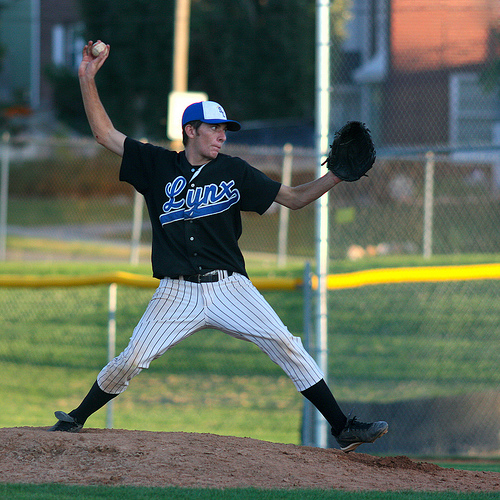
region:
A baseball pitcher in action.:
[45, 35, 390, 456]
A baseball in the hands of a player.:
[85, 37, 105, 53]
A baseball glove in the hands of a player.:
[320, 115, 375, 180]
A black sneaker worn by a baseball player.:
[325, 415, 385, 450]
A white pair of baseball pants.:
[90, 265, 321, 391]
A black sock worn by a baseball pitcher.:
[295, 375, 350, 425]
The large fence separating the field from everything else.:
[0, 0, 495, 462]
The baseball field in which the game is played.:
[0, 425, 496, 496]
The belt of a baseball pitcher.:
[165, 270, 235, 283]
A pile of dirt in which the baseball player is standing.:
[0, 427, 492, 484]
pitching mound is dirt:
[21, 400, 323, 489]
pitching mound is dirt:
[66, 430, 316, 497]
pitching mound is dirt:
[89, 397, 426, 499]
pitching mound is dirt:
[73, 371, 443, 496]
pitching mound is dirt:
[77, 398, 245, 492]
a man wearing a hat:
[123, 65, 293, 302]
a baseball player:
[6, 14, 416, 454]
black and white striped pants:
[103, 250, 375, 379]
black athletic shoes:
[28, 395, 453, 466]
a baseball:
[43, 27, 210, 139]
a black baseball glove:
[271, 87, 406, 228]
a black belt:
[111, 250, 349, 339]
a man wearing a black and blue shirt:
[68, 28, 363, 316]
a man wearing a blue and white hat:
[118, 75, 304, 227]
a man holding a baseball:
[52, 27, 431, 251]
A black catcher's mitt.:
[323, 118, 376, 184]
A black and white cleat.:
[330, 415, 386, 450]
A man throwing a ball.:
[48, 35, 388, 452]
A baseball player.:
[48, 38, 388, 450]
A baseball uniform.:
[107, 135, 318, 412]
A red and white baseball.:
[88, 37, 108, 58]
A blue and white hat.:
[180, 100, 240, 132]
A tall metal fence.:
[312, 30, 497, 466]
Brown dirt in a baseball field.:
[1, 426, 497, 491]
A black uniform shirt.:
[118, 134, 282, 283]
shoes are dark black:
[279, 377, 426, 466]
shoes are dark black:
[313, 387, 415, 449]